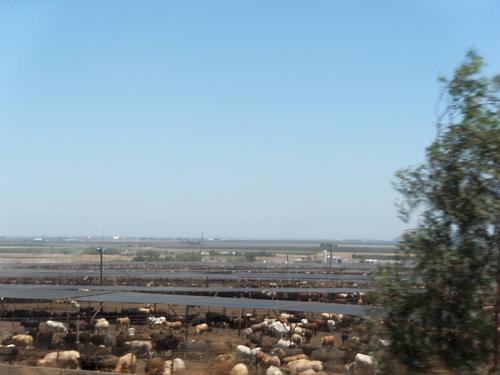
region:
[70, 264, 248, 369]
livestock are very visible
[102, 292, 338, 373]
livestock are very visible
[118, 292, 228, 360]
livestock are very visible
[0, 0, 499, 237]
a clear blue sky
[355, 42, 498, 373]
a leafy green tree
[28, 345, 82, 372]
a white cow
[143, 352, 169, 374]
a brown cow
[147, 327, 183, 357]
a black cow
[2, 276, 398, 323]
a gray roof over the lot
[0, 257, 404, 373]
a brown dirt lot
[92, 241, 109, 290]
a brown wooden pole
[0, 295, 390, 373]
a lot filled with cows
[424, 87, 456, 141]
the branch of a tree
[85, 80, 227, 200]
the sky is blue and clear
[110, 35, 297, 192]
the boots are black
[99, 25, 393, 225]
the boots are black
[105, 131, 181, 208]
the boots are black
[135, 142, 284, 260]
the boots are black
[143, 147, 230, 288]
the boots are black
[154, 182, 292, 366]
the boots are black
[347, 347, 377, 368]
white cow in field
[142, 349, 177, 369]
brown car in field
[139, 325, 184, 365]
black cow in field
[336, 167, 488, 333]
tall green tree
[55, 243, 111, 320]
light on a pole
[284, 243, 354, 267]
building in the back ground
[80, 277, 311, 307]
silver roof for shade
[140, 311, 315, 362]
cows in a field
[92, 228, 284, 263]
green trees in back ground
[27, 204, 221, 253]
buildings in the distance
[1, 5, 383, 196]
a blue clear sky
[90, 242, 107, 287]
a pole sitting across the water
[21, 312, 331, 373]
a group of cows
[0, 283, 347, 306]
a body of blue water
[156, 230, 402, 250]
a cement freeway in the background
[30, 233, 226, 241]
farms off into the distance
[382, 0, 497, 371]
a large pine tree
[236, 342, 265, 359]
a white cow grazing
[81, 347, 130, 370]
a brown cow grazing on grass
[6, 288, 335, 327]
a brown fence to keep the cows in